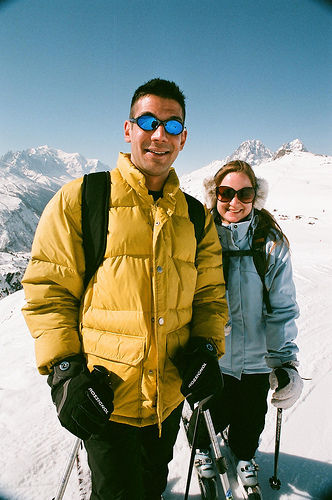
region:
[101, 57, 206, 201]
a man wearing sunglasses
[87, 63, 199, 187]
a man with black hair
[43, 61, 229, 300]
a man wearing a backpack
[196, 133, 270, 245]
a woman wearing ear muffs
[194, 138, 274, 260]
a woman wearing sunglasses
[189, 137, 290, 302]
a woman wearing a backpack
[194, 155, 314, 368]
a woman wearing a blue jacket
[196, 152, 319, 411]
a woman wearing white gloves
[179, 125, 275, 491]
a woman skiing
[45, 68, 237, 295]
a man wearing a yellow jacket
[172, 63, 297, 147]
The sky is blue and clear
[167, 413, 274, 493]
The girl has skis on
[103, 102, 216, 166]
The man has sunglasses on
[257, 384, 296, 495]
The girl has ski poles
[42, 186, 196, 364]
The man's coat is yellow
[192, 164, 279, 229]
The woman has sunglasses on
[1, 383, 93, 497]
The snow is white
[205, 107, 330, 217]
Mountains are in the back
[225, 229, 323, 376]
The woman's coat is blue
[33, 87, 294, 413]
The people are together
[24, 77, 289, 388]
two smiling people posing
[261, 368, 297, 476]
pole in gloved hand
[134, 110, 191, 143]
sunglasses on man's face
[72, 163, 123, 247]
black strap on shoulder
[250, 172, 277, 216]
ear muff on head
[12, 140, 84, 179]
mountain top covered in snow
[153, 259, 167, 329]
metal buttons on coat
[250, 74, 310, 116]
blue of daytime sky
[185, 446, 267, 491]
gray boots on skis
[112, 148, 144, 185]
collar of yellow coat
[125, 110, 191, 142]
Reflection of photographer in skier's goggles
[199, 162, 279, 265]
Woman wearing sunglasses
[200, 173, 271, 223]
Person wearing white ear muffs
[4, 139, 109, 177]
Snow-covered mountains on sunny day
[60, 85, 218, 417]
Man wearing yellow ski jacket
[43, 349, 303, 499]
Two people holding ski poles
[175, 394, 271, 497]
Skier wearing light blue ski boots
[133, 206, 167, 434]
Person's unbuttoned yellow ski jacket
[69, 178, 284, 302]
Two people carrying backpacks on their backs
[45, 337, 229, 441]
Person wearing large black gloves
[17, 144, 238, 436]
A yellow ski jacket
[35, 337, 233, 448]
Black gloves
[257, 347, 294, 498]
A ski pole to the right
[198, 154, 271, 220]
Furry type ear muffs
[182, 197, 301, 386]
A light blue winter coat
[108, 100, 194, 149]
Sunglasses being worn by a man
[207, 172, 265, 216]
Sunglasses being worn by a woman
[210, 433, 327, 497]
Shadow of the woman skier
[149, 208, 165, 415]
Snaps on a yellow coat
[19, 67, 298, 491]
2 skiers smiling